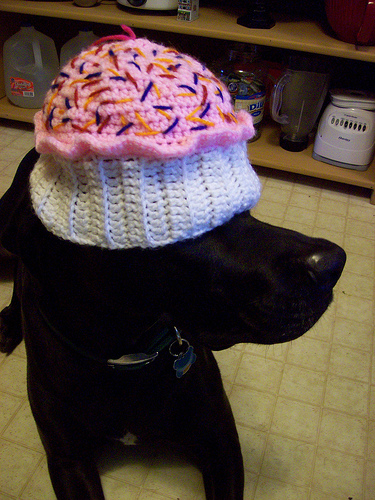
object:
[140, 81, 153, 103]
yarn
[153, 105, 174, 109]
sprinkle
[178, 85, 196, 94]
sprinkle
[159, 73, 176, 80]
sprinkle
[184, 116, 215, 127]
sprinkle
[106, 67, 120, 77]
sprinkle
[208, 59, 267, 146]
glass bottle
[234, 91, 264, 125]
label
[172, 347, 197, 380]
tag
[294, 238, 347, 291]
nose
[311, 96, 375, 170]
blender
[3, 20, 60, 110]
plastic jug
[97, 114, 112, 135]
yarn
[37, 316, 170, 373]
collar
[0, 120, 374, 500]
floor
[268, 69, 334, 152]
pitcher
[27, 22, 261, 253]
beanie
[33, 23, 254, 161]
crocheted hat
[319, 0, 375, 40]
containre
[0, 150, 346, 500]
dog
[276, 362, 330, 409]
tile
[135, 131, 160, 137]
yarn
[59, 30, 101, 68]
bottle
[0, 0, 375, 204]
shelves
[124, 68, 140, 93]
yarn